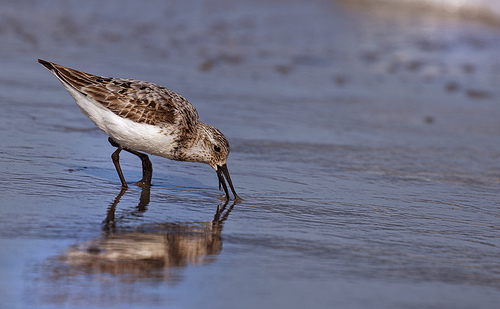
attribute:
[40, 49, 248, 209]
bird — brown, white, wet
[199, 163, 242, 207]
beek — open, black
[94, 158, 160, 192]
legs — black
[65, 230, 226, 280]
reflection — wet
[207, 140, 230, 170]
eye — black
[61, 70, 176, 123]
wing — brown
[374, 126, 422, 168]
water — brown, wet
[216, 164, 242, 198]
beak — black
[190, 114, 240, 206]
head — brown